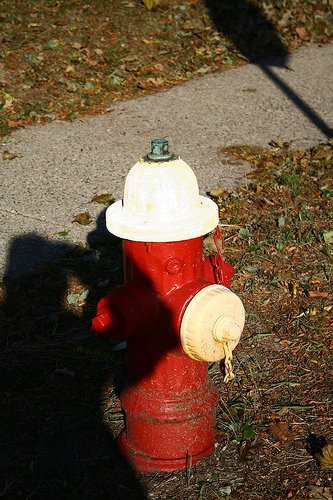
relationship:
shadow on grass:
[2, 205, 179, 498] [0, 145, 332, 498]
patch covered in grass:
[0, 0, 329, 492] [245, 180, 329, 287]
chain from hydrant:
[222, 341, 234, 385] [105, 138, 246, 476]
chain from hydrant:
[208, 228, 224, 286] [92, 137, 245, 471]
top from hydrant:
[140, 137, 182, 160] [92, 137, 245, 471]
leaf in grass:
[265, 410, 297, 444] [67, 152, 331, 497]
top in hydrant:
[145, 137, 175, 163] [45, 98, 280, 421]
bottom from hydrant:
[81, 227, 235, 466] [136, 128, 273, 401]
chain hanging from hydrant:
[222, 341, 234, 385] [77, 140, 245, 462]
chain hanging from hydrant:
[208, 228, 224, 286] [77, 140, 245, 462]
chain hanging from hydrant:
[208, 228, 224, 286] [92, 137, 245, 471]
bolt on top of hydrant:
[141, 133, 174, 159] [92, 137, 245, 471]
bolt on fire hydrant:
[145, 240, 154, 245] [86, 136, 249, 472]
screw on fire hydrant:
[146, 246, 152, 254] [86, 136, 249, 472]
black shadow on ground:
[152, 23, 323, 75] [0, 1, 332, 496]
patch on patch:
[0, 0, 332, 499] [0, 0, 332, 499]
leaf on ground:
[150, 68, 163, 86] [0, 1, 332, 496]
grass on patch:
[271, 156, 313, 195] [0, 0, 332, 499]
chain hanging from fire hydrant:
[222, 341, 234, 385] [86, 136, 249, 472]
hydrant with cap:
[114, 165, 207, 375] [99, 131, 226, 247]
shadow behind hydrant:
[2, 205, 179, 498] [92, 137, 245, 471]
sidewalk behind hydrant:
[2, 41, 331, 295] [92, 137, 245, 471]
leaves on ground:
[0, 0, 331, 138] [239, 145, 321, 493]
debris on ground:
[165, 71, 281, 147] [12, 3, 303, 493]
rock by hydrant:
[215, 483, 235, 496] [62, 140, 254, 460]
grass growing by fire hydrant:
[237, 352, 322, 490] [86, 136, 249, 472]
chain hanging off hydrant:
[217, 331, 240, 378] [77, 128, 254, 473]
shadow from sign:
[201, 3, 331, 136] [201, 0, 297, 72]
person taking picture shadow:
[1, 201, 179, 491] [14, 214, 172, 494]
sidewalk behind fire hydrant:
[2, 41, 331, 295] [86, 136, 249, 472]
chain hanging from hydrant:
[187, 229, 239, 298] [57, 121, 272, 440]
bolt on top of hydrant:
[146, 137, 175, 163] [92, 137, 245, 471]